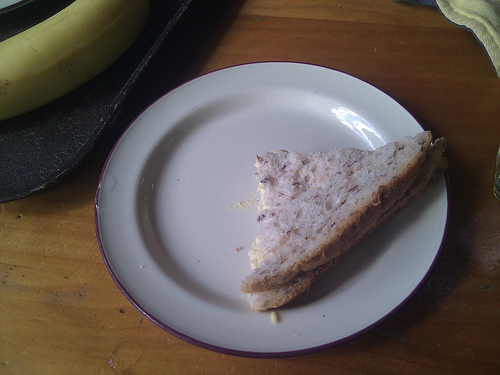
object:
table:
[2, 1, 498, 374]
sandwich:
[239, 131, 447, 310]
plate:
[92, 62, 449, 360]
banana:
[1, 0, 159, 122]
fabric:
[437, 2, 498, 72]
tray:
[1, 1, 192, 205]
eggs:
[247, 177, 272, 271]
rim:
[252, 62, 365, 92]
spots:
[4, 75, 45, 98]